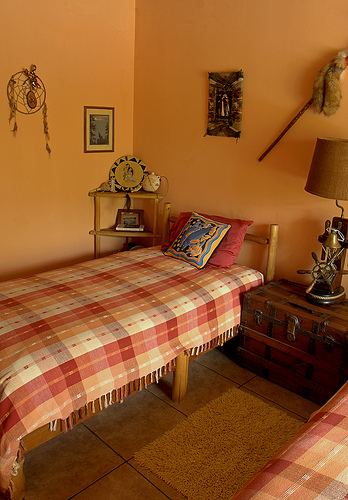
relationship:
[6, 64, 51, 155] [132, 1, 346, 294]
dream catcher hung on wall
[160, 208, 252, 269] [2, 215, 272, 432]
pillow on bed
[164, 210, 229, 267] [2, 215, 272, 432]
pillow on bed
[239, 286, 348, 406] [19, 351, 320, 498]
cabinet on floor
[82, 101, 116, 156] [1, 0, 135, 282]
brown oven on wall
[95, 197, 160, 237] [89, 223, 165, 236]
photo on shelf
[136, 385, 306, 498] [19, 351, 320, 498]
mat on floor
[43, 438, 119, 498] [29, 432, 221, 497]
tiles on floor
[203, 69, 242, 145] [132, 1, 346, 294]
picture on wall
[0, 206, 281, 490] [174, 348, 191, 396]
bed has leg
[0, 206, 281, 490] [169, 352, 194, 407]
bed has leg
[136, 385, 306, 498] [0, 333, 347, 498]
mat on floor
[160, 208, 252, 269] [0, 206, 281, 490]
pillow on bed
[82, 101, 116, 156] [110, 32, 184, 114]
brown oven on wall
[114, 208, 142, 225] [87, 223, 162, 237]
photo on shelf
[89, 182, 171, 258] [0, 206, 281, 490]
cabinet next to bed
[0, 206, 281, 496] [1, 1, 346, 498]
bed in room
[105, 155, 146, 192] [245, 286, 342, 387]
plate on cabinet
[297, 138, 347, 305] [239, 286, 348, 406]
lamp on cabinet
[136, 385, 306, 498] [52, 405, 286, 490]
mat on floor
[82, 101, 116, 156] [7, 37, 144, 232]
brown oven on wall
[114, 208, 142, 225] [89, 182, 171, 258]
photo on cabinet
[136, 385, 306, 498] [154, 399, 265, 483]
mat on floor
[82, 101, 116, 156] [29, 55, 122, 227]
brown oven hanging on wall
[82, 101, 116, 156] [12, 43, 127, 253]
brown oven hanging on wall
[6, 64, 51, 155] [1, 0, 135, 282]
dream catcher hanging on wall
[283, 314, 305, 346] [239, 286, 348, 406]
lock on cabinet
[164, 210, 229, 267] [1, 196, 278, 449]
pillow on bed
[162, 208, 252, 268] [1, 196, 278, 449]
pillow on bed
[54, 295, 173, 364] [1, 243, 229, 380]
comforter on bed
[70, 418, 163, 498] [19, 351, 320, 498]
lines on floor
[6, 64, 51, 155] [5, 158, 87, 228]
dream catcher on wall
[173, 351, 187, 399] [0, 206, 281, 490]
leg of bed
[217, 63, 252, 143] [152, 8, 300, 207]
picture on wall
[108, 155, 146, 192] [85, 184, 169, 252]
plate on stand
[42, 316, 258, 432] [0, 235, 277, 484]
fringe on blanket